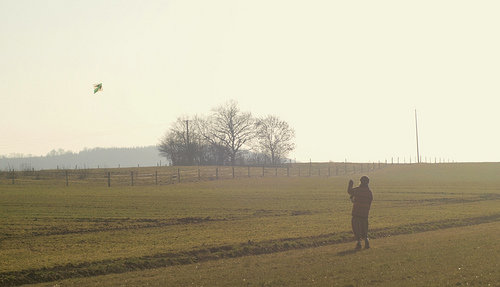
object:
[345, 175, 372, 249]
man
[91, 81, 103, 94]
kite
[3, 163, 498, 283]
field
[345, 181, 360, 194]
arm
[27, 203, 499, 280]
drench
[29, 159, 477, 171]
gate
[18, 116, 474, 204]
background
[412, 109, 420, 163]
pole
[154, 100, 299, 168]
tree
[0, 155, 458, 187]
fence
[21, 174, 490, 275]
grass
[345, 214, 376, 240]
shorts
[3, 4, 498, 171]
sky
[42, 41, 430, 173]
air